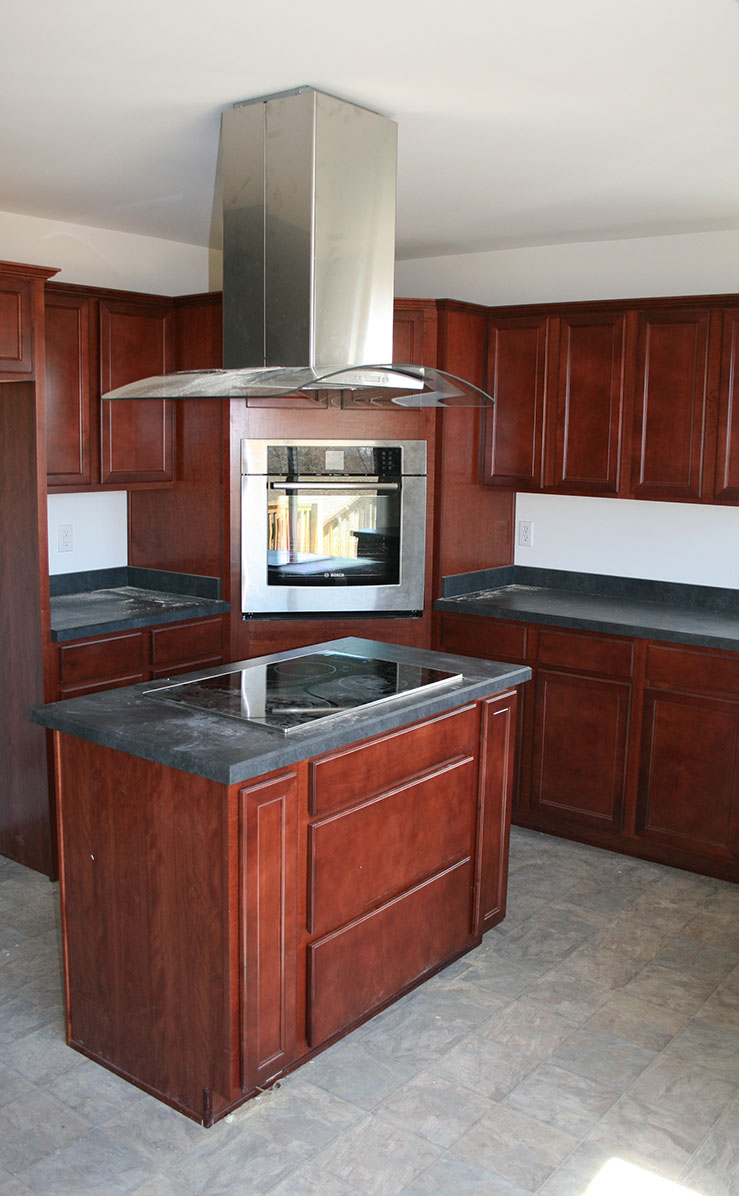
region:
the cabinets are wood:
[0, 256, 737, 1123]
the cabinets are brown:
[0, 253, 738, 1128]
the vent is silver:
[111, 88, 499, 409]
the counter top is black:
[64, 627, 524, 788]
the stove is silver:
[244, 437, 430, 613]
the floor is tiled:
[1, 828, 736, 1193]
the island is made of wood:
[56, 631, 533, 1129]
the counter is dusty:
[45, 637, 529, 787]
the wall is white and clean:
[505, 487, 736, 592]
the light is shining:
[575, 1153, 702, 1193]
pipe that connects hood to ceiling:
[205, 88, 415, 363]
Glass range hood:
[86, 351, 534, 430]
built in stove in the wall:
[229, 420, 448, 631]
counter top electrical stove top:
[144, 638, 515, 775]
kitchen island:
[32, 619, 593, 1136]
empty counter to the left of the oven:
[27, 551, 227, 652]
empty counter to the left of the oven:
[430, 534, 735, 663]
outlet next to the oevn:
[507, 503, 548, 560]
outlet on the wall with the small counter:
[50, 510, 103, 570]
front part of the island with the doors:
[167, 681, 522, 1105]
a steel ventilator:
[97, 86, 506, 416]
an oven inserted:
[234, 427, 434, 619]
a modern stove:
[138, 635, 475, 730]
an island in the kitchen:
[44, 629, 535, 1127]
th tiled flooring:
[3, 824, 733, 1192]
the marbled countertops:
[54, 566, 738, 773]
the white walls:
[4, 211, 736, 588]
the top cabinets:
[0, 265, 735, 507]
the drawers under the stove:
[299, 697, 486, 1050]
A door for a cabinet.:
[39, 293, 91, 486]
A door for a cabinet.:
[97, 301, 175, 483]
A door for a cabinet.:
[482, 312, 548, 488]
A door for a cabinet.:
[551, 313, 628, 496]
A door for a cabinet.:
[631, 304, 709, 498]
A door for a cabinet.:
[527, 667, 632, 834]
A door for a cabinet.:
[237, 770, 298, 1090]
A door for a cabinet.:
[471, 689, 517, 934]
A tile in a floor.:
[514, 968, 616, 1028]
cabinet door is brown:
[97, 302, 178, 479]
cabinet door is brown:
[239, 771, 296, 1085]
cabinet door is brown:
[309, 754, 473, 936]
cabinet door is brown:
[300, 855, 474, 1045]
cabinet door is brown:
[533, 665, 624, 833]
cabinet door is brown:
[635, 685, 738, 863]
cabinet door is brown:
[53, 628, 143, 680]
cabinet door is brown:
[150, 616, 227, 666]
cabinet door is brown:
[533, 624, 634, 677]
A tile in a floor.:
[308, 1040, 418, 1110]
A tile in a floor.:
[448, 1100, 582, 1191]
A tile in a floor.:
[4, 1020, 91, 1083]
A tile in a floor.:
[5, 1086, 93, 1173]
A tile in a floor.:
[15, 1126, 155, 1193]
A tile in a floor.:
[516, 970, 614, 1021]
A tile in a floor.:
[625, 1051, 735, 1121]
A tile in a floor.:
[0, 876, 65, 931]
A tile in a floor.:
[505, 859, 582, 901]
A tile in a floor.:
[538, 839, 614, 874]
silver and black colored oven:
[237, 436, 431, 620]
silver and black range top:
[142, 646, 486, 733]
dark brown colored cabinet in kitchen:
[237, 770, 303, 1085]